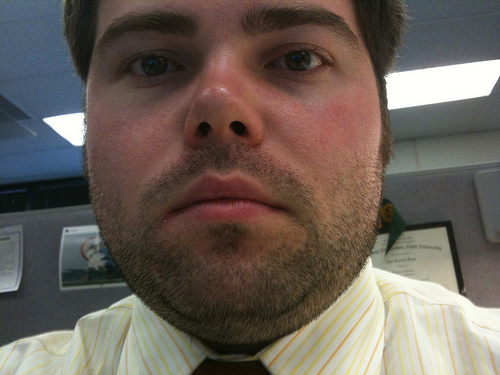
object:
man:
[8, 1, 488, 375]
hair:
[61, 1, 407, 69]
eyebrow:
[93, 10, 202, 50]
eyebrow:
[242, 2, 364, 46]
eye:
[120, 49, 187, 80]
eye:
[265, 45, 341, 75]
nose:
[184, 47, 264, 154]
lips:
[185, 170, 264, 201]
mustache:
[143, 143, 320, 223]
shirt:
[0, 261, 499, 374]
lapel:
[115, 277, 388, 361]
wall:
[2, 153, 497, 346]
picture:
[58, 225, 127, 290]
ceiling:
[1, 2, 499, 190]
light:
[42, 106, 96, 150]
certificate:
[361, 220, 462, 296]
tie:
[190, 356, 267, 374]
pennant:
[377, 196, 404, 254]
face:
[92, 9, 369, 281]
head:
[70, 2, 412, 345]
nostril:
[195, 120, 212, 137]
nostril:
[229, 120, 251, 137]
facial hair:
[85, 132, 385, 347]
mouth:
[167, 169, 292, 232]